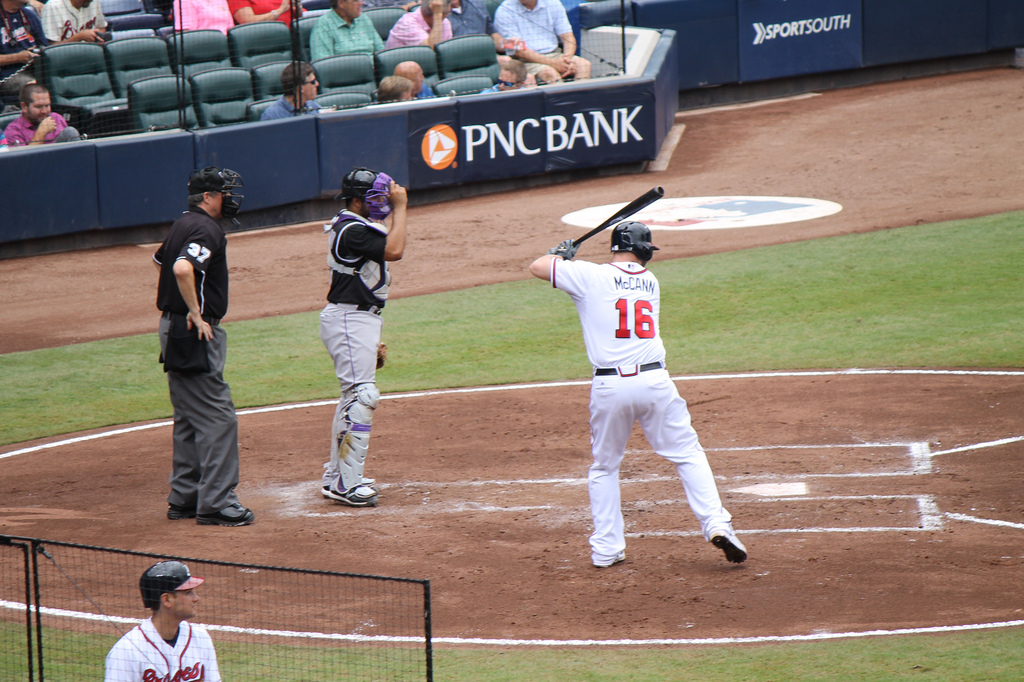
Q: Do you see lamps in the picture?
A: No, there are no lamps.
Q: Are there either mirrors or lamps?
A: No, there are no lamps or mirrors.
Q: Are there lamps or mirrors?
A: No, there are no lamps or mirrors.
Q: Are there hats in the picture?
A: Yes, there is a hat.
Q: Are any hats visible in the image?
A: Yes, there is a hat.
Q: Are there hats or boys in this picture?
A: Yes, there is a hat.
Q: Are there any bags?
A: No, there are no bags.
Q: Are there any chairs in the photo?
A: Yes, there is a chair.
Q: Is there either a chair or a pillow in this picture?
A: Yes, there is a chair.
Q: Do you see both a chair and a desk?
A: No, there is a chair but no desks.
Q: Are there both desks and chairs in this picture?
A: No, there is a chair but no desks.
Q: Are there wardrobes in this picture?
A: No, there are no wardrobes.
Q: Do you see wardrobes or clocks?
A: No, there are no wardrobes or clocks.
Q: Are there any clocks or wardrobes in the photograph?
A: No, there are no wardrobes or clocks.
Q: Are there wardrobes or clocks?
A: No, there are no wardrobes or clocks.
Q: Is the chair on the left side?
A: Yes, the chair is on the left of the image.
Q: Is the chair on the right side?
A: No, the chair is on the left of the image.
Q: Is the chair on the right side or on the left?
A: The chair is on the left of the image.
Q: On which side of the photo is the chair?
A: The chair is on the left of the image.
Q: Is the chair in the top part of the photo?
A: Yes, the chair is in the top of the image.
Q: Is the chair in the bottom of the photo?
A: No, the chair is in the top of the image.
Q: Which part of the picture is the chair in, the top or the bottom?
A: The chair is in the top of the image.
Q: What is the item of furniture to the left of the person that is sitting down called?
A: The piece of furniture is a chair.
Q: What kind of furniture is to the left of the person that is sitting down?
A: The piece of furniture is a chair.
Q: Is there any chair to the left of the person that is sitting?
A: Yes, there is a chair to the left of the person.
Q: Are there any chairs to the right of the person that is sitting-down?
A: No, the chair is to the left of the person.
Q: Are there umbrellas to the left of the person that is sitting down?
A: No, there is a chair to the left of the person.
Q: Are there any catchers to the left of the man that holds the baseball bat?
A: Yes, there is a catcher to the left of the man.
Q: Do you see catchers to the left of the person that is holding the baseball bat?
A: Yes, there is a catcher to the left of the man.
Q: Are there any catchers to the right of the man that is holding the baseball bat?
A: No, the catcher is to the left of the man.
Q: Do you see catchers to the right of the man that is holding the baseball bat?
A: No, the catcher is to the left of the man.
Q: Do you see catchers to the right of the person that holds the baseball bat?
A: No, the catcher is to the left of the man.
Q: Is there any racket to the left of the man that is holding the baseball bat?
A: No, there is a catcher to the left of the man.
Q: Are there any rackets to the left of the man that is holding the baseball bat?
A: No, there is a catcher to the left of the man.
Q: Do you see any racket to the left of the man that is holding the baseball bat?
A: No, there is a catcher to the left of the man.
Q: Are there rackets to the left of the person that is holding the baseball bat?
A: No, there is a catcher to the left of the man.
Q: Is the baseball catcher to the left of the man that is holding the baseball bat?
A: Yes, the catcher is to the left of the man.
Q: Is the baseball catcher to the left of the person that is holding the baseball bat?
A: Yes, the catcher is to the left of the man.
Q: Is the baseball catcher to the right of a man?
A: No, the catcher is to the left of a man.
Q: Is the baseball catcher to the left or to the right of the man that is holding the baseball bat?
A: The catcher is to the left of the man.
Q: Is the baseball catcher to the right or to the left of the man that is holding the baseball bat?
A: The catcher is to the left of the man.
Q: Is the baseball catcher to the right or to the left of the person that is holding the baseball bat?
A: The catcher is to the left of the man.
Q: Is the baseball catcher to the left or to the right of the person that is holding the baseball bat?
A: The catcher is to the left of the man.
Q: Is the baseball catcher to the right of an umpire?
A: Yes, the catcher is to the right of an umpire.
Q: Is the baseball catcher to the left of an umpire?
A: No, the catcher is to the right of an umpire.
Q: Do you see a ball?
A: No, there are no balls.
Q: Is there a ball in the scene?
A: No, there are no balls.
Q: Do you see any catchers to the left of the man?
A: Yes, there is a catcher to the left of the man.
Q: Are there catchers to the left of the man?
A: Yes, there is a catcher to the left of the man.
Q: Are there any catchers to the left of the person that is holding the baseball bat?
A: Yes, there is a catcher to the left of the man.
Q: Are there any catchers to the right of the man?
A: No, the catcher is to the left of the man.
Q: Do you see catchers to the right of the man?
A: No, the catcher is to the left of the man.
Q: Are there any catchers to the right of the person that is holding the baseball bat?
A: No, the catcher is to the left of the man.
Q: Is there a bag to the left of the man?
A: No, there is a catcher to the left of the man.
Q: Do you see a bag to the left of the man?
A: No, there is a catcher to the left of the man.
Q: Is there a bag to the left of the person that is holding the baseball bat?
A: No, there is a catcher to the left of the man.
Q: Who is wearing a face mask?
A: The catcher is wearing a face mask.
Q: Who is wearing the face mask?
A: The catcher is wearing a face mask.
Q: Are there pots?
A: No, there are no pots.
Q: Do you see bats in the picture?
A: Yes, there is a bat.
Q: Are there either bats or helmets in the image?
A: Yes, there is a bat.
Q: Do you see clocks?
A: No, there are no clocks.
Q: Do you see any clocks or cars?
A: No, there are no clocks or cars.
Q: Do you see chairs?
A: Yes, there is a chair.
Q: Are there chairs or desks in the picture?
A: Yes, there is a chair.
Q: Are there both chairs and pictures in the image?
A: No, there is a chair but no pictures.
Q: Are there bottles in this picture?
A: No, there are no bottles.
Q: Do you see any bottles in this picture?
A: No, there are no bottles.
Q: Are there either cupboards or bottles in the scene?
A: No, there are no bottles or cupboards.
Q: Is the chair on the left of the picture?
A: Yes, the chair is on the left of the image.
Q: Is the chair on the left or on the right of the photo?
A: The chair is on the left of the image.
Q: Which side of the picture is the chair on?
A: The chair is on the left of the image.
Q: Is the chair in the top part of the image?
A: Yes, the chair is in the top of the image.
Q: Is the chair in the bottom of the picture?
A: No, the chair is in the top of the image.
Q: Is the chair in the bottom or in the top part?
A: The chair is in the top of the image.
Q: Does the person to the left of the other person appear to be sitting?
A: Yes, the person is sitting.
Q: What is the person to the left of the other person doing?
A: The person is sitting.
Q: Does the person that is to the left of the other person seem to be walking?
A: No, the person is sitting.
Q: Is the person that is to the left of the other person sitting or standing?
A: The person is sitting.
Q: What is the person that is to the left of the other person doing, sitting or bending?
A: The person is sitting.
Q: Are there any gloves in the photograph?
A: Yes, there are gloves.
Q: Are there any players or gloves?
A: Yes, there are gloves.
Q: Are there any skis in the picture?
A: No, there are no skis.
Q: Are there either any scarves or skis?
A: No, there are no skis or scarves.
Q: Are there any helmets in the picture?
A: Yes, there is a helmet.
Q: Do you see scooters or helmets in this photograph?
A: Yes, there is a helmet.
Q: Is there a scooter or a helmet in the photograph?
A: Yes, there is a helmet.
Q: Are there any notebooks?
A: No, there are no notebooks.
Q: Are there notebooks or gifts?
A: No, there are no notebooks or gifts.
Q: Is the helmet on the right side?
A: No, the helmet is on the left of the image.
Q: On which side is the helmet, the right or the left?
A: The helmet is on the left of the image.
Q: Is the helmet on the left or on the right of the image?
A: The helmet is on the left of the image.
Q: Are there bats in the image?
A: Yes, there is a bat.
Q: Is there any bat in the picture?
A: Yes, there is a bat.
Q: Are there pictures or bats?
A: Yes, there is a bat.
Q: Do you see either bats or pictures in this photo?
A: Yes, there is a bat.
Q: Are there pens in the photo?
A: No, there are no pens.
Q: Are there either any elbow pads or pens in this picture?
A: No, there are no pens or elbow pads.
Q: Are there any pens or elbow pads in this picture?
A: No, there are no pens or elbow pads.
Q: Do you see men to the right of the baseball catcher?
A: Yes, there is a man to the right of the catcher.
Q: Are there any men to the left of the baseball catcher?
A: No, the man is to the right of the catcher.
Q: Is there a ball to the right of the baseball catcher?
A: No, there is a man to the right of the catcher.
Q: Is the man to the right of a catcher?
A: Yes, the man is to the right of a catcher.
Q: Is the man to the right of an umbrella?
A: No, the man is to the right of a catcher.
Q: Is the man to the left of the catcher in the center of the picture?
A: No, the man is to the right of the catcher.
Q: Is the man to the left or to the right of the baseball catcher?
A: The man is to the right of the catcher.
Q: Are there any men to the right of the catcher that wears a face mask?
A: Yes, there is a man to the right of the catcher.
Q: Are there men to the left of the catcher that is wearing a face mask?
A: No, the man is to the right of the catcher.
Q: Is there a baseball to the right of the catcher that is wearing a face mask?
A: No, there is a man to the right of the catcher.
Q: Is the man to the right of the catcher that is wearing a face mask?
A: Yes, the man is to the right of the catcher.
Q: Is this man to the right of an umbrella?
A: No, the man is to the right of the catcher.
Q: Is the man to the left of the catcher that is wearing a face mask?
A: No, the man is to the right of the catcher.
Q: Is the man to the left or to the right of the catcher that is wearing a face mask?
A: The man is to the right of the catcher.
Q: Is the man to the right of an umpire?
A: Yes, the man is to the right of an umpire.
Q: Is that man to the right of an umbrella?
A: No, the man is to the right of an umpire.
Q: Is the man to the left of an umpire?
A: No, the man is to the right of an umpire.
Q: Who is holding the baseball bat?
A: The man is holding the baseball bat.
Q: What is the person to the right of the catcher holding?
A: The man is holding the baseball bat.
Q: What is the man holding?
A: The man is holding the baseball bat.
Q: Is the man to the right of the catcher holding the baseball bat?
A: Yes, the man is holding the baseball bat.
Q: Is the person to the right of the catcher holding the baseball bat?
A: Yes, the man is holding the baseball bat.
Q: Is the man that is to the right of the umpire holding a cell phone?
A: No, the man is holding the baseball bat.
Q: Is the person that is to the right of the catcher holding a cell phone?
A: No, the man is holding the baseball bat.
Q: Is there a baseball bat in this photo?
A: Yes, there is a baseball bat.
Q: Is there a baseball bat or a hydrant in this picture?
A: Yes, there is a baseball bat.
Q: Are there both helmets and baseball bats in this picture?
A: Yes, there are both a baseball bat and a helmet.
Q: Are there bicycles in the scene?
A: No, there are no bicycles.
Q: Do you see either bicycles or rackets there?
A: No, there are no bicycles or rackets.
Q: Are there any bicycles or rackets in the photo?
A: No, there are no bicycles or rackets.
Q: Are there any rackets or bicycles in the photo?
A: No, there are no bicycles or rackets.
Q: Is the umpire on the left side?
A: Yes, the umpire is on the left of the image.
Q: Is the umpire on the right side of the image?
A: No, the umpire is on the left of the image.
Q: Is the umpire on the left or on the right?
A: The umpire is on the left of the image.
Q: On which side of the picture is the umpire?
A: The umpire is on the left of the image.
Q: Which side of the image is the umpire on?
A: The umpire is on the left of the image.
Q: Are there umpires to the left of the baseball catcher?
A: Yes, there is an umpire to the left of the catcher.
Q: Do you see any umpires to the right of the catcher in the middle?
A: No, the umpire is to the left of the catcher.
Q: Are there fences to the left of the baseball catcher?
A: No, there is an umpire to the left of the catcher.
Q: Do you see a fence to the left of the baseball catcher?
A: No, there is an umpire to the left of the catcher.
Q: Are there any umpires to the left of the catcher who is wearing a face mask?
A: Yes, there is an umpire to the left of the catcher.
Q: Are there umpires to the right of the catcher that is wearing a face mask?
A: No, the umpire is to the left of the catcher.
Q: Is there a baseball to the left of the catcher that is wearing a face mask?
A: No, there is an umpire to the left of the catcher.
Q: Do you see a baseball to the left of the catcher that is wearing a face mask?
A: No, there is an umpire to the left of the catcher.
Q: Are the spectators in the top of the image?
A: Yes, the spectators are in the top of the image.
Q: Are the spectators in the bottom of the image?
A: No, the spectators are in the top of the image.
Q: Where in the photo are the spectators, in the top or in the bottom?
A: The spectators are in the top of the image.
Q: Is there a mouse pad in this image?
A: No, there are no mouse pads.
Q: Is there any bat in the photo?
A: Yes, there is a bat.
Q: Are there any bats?
A: Yes, there is a bat.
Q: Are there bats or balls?
A: Yes, there is a bat.